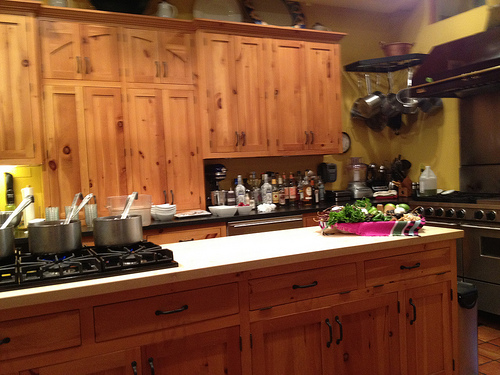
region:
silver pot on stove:
[92, 188, 146, 250]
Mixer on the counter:
[345, 155, 372, 200]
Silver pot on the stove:
[20, 205, 83, 255]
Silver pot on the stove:
[0, 199, 28, 261]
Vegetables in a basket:
[320, 199, 429, 235]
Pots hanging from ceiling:
[332, 42, 442, 142]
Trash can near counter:
[445, 268, 482, 373]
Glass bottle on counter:
[298, 168, 315, 210]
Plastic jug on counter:
[412, 160, 445, 202]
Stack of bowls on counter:
[146, 200, 178, 232]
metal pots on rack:
[344, 37, 439, 137]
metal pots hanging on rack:
[343, 42, 442, 139]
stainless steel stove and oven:
[414, 183, 499, 301]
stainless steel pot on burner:
[99, 192, 148, 251]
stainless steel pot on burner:
[31, 187, 90, 254]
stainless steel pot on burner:
[1, 196, 23, 261]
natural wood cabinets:
[3, 1, 348, 211]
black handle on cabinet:
[151, 301, 192, 317]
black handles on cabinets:
[321, 314, 347, 353]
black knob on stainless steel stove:
[454, 206, 465, 224]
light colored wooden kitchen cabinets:
[0, 0, 347, 235]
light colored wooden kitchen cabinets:
[0, 239, 460, 373]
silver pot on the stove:
[28, 192, 95, 251]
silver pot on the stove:
[93, 192, 143, 246]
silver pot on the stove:
[0, 195, 35, 257]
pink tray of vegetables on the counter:
[315, 196, 425, 238]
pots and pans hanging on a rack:
[343, 53, 438, 133]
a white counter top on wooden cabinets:
[0, 221, 464, 311]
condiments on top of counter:
[235, 168, 327, 208]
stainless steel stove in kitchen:
[411, 193, 498, 317]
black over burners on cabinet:
[0, 240, 180, 292]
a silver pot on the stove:
[27, 190, 92, 255]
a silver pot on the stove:
[93, 191, 141, 248]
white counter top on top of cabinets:
[0, 223, 464, 308]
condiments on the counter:
[228, 170, 327, 207]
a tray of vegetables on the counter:
[313, 200, 425, 237]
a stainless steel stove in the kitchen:
[405, 191, 498, 317]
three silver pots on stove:
[1, 203, 164, 256]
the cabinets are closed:
[90, 44, 352, 206]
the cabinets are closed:
[37, 25, 373, 283]